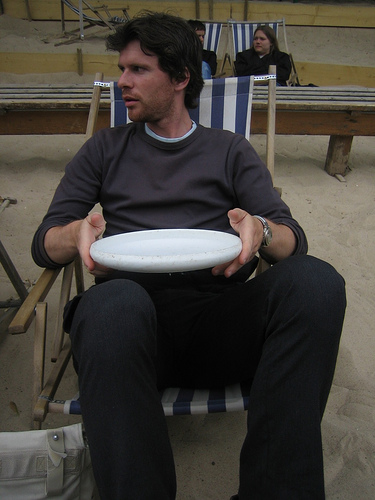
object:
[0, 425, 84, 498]
purse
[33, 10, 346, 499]
man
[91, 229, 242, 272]
frisbee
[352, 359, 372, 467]
sand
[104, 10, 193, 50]
hair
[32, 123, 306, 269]
sweater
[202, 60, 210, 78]
jeans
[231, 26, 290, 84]
woman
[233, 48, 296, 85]
jacket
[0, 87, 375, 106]
board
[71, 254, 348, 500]
pants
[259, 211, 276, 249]
watch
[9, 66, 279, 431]
chair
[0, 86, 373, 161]
bench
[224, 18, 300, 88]
chair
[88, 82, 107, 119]
bracket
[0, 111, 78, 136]
beam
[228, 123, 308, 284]
arm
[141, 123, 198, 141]
shirt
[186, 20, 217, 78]
man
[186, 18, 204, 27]
hair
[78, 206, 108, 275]
hand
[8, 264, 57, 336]
arm rest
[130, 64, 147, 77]
eye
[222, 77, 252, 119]
stripes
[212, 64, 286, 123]
back